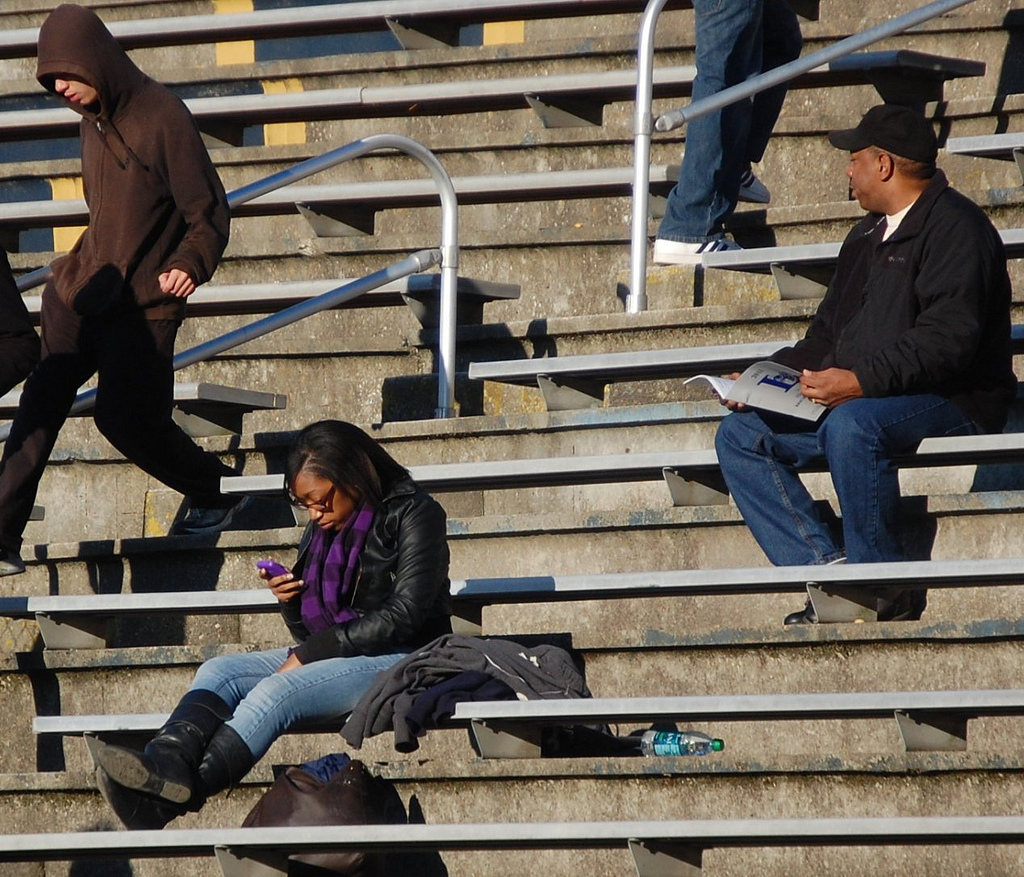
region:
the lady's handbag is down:
[295, 755, 435, 870]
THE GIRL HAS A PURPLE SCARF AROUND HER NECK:
[252, 529, 376, 603]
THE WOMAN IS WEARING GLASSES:
[275, 474, 389, 528]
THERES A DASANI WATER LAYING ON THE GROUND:
[624, 718, 735, 761]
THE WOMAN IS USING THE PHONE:
[240, 531, 292, 617]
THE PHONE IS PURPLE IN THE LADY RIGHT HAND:
[234, 547, 342, 615]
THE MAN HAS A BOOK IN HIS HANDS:
[692, 335, 842, 408]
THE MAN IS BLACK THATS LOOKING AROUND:
[793, 98, 972, 258]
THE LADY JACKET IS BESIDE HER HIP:
[334, 619, 607, 733]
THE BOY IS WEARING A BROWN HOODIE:
[2, 16, 142, 252]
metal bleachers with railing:
[226, 16, 661, 437]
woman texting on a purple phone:
[78, 405, 500, 861]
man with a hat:
[687, 96, 1016, 612]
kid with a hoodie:
[2, 1, 234, 599]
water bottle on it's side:
[634, 716, 748, 761]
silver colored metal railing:
[282, 128, 526, 413]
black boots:
[68, 668, 262, 834]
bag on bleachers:
[232, 748, 467, 870]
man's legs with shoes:
[633, 10, 811, 276]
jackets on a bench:
[343, 617, 610, 761]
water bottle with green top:
[623, 706, 767, 796]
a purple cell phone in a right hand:
[250, 545, 304, 612]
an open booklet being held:
[688, 348, 847, 424]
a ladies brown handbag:
[255, 748, 389, 862]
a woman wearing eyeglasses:
[268, 418, 395, 533]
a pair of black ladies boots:
[76, 674, 247, 821]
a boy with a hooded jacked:
[19, 4, 165, 151]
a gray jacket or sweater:
[331, 626, 622, 754]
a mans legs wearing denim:
[695, 425, 975, 558]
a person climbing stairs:
[613, 17, 804, 268]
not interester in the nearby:
[84, 397, 455, 830]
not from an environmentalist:
[623, 703, 744, 754]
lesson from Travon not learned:
[1, 2, 230, 578]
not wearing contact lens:
[231, 415, 478, 577]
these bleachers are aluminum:
[737, 599, 1022, 857]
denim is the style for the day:
[260, 4, 987, 830]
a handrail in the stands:
[253, 57, 544, 419]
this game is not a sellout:
[134, 70, 953, 813]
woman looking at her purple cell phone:
[215, 407, 476, 758]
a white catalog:
[671, 313, 907, 466]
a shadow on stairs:
[35, 492, 255, 669]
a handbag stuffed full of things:
[244, 734, 448, 874]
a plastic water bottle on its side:
[623, 710, 744, 768]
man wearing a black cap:
[797, 97, 985, 249]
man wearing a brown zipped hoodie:
[22, 3, 235, 567]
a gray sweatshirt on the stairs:
[338, 617, 624, 741]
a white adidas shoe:
[629, 201, 765, 287]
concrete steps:
[662, 740, 1021, 829]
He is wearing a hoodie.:
[30, 4, 243, 255]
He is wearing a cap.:
[811, 93, 974, 224]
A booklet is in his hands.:
[662, 345, 878, 454]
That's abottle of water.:
[614, 709, 729, 779]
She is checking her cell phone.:
[218, 535, 333, 628]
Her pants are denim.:
[206, 639, 396, 715]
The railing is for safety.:
[238, 135, 474, 415]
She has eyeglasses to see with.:
[263, 438, 401, 540]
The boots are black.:
[60, 703, 242, 824]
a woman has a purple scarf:
[289, 519, 379, 637]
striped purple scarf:
[292, 491, 357, 624]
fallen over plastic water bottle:
[620, 721, 722, 751]